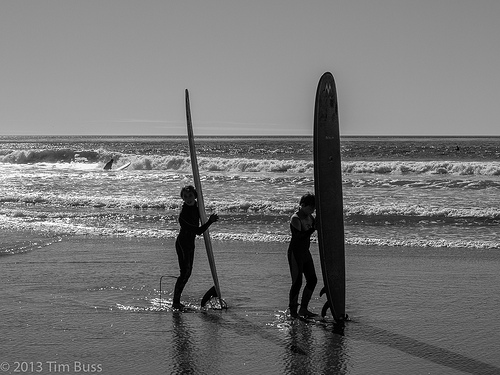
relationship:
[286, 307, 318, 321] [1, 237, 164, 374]
girl's feet in water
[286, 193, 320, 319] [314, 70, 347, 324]
girl next to a surfboard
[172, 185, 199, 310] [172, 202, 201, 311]
girl has a wetsuit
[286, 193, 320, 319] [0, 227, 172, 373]
surfer on beach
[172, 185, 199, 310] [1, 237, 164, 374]
surfer in water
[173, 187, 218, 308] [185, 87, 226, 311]
girl holding surfboard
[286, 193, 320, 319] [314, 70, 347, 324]
surfer with her surfboard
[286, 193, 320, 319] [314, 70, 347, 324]
girl with her surfboard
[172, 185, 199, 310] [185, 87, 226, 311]
surfer with a surfboard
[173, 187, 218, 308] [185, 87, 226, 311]
surfer holding surfboard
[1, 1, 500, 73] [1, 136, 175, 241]
sky over ocean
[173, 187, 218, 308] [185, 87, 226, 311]
surfer with a sufboard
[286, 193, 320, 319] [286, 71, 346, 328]
surfer going to surf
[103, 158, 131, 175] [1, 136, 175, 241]
surfer in ocean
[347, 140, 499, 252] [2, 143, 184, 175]
ocean has waves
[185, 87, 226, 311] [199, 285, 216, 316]
surfboard has a fin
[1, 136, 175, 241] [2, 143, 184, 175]
ocean has rough waves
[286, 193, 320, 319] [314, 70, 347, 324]
surfers with surfboards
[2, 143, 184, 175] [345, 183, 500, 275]
waves crashing on shore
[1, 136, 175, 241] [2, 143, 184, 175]
ocean has waves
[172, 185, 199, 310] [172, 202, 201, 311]
surfer has a wetsuit